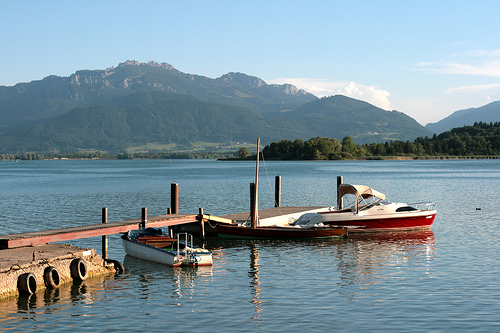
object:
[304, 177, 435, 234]
boat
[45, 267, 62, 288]
wheel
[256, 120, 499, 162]
trees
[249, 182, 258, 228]
post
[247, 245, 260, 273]
reflection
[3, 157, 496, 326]
water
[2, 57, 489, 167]
mountains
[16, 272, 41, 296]
black tires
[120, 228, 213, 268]
boat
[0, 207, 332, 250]
boardwalk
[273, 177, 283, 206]
dock beam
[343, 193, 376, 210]
railings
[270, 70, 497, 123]
cloud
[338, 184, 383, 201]
covering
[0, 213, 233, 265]
dock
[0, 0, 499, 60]
sky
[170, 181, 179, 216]
posts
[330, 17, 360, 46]
part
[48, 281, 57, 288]
part